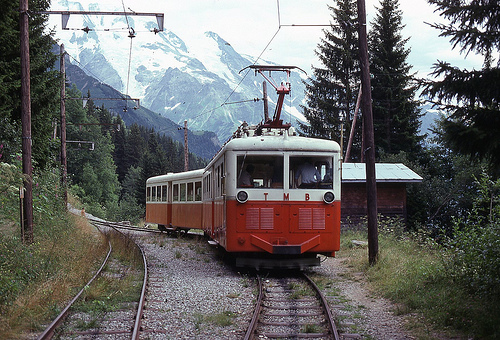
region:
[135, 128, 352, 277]
red and white train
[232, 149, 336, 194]
windshield of the train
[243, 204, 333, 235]
vents on the front of train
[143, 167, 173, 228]
last car on the train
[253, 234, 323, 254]
bumper on the train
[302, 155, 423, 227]
building near the tracks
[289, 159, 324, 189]
man standing on the train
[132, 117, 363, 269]
old red and white train on track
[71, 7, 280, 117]
snow covered mountain in the distance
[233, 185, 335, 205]
headlights on the old train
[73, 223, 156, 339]
grass covered train track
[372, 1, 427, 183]
pine tree along the tracks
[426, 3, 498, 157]
pine tree along the tracks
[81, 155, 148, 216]
pine tree along the tracks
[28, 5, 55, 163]
pine tree along the tracks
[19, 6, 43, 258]
wooden electrical pole along the track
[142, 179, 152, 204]
square window on train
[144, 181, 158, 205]
square window on train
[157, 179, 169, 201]
square window on train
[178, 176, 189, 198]
square window on train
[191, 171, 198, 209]
square window on train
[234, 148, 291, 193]
square window on train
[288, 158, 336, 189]
square window on train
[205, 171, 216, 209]
square window on train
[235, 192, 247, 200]
The left headlight.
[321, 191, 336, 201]
The right headlight.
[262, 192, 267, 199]
The letter T on the front of the train.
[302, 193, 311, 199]
The letter B on the front of the train.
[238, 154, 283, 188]
The left front window of the train.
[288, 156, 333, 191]
The right front window of the train.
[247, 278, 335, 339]
The tracks the train is driving on.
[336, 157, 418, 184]
The white roof of the building on the right.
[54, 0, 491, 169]
The mountain in the background.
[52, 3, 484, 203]
Mountains in the background.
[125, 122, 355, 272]
A train.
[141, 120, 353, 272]
A white and orange train.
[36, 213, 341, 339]
two sets of railroad tracks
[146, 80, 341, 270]
train is red and white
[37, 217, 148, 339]
weeds are growing between the tracks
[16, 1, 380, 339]
poles supporting electrical wires that are above the train tracks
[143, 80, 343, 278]
train conductor visible behind train windshield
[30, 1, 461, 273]
snow on mountains behind train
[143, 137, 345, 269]
The train on the tracks.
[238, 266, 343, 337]
The tracks on the ground.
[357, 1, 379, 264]
The wooden pole beside the train.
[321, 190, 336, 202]
The round light on the train.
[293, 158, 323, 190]
The conductor in the window.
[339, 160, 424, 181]
The roof of the building.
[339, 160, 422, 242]
The building behind the post.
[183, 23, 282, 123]
The cable hanging above the train.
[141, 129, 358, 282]
A red and white train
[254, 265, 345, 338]
Train tracks running through the countryside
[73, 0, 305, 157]
A white snowy mountain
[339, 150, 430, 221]
A small building next to a train track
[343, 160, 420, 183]
A white roof on a building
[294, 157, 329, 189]
A man driving a train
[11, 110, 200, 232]
Tall fir trees on a hillside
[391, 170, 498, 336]
Green bushes on a hillside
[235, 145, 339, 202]
The front of a red train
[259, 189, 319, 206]
Three red letters on the front of train